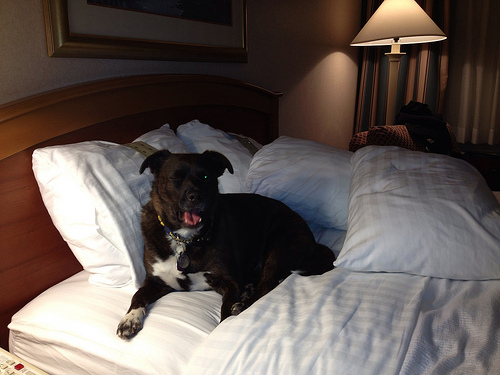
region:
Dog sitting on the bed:
[116, 161, 343, 338]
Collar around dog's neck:
[152, 198, 215, 253]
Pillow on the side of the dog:
[29, 116, 206, 282]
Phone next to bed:
[0, 340, 43, 374]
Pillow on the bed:
[344, 133, 497, 283]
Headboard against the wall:
[0, 75, 296, 350]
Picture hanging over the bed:
[32, 2, 268, 71]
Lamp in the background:
[352, 3, 441, 137]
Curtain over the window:
[442, 3, 497, 154]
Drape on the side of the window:
[354, 1, 454, 151]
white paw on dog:
[118, 291, 165, 346]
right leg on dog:
[128, 275, 173, 332]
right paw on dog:
[101, 294, 149, 349]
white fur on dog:
[143, 260, 190, 279]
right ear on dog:
[139, 155, 186, 177]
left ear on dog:
[209, 144, 238, 169]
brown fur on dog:
[158, 174, 187, 214]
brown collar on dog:
[160, 220, 199, 254]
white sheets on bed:
[230, 312, 379, 368]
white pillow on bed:
[331, 162, 458, 289]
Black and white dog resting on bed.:
[115, 148, 334, 341]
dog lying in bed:
[113, 143, 343, 341]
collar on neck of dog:
[148, 204, 224, 279]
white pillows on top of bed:
[29, 120, 497, 302]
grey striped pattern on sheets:
[206, 285, 383, 373]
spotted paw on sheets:
[105, 300, 157, 344]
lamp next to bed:
[340, 0, 457, 143]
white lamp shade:
[343, 0, 458, 57]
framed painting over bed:
[36, 0, 272, 74]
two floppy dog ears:
[128, 143, 246, 178]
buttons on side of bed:
[2, 345, 48, 373]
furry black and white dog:
[113, 145, 347, 347]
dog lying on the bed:
[126, 144, 338, 342]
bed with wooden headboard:
[0, 73, 498, 374]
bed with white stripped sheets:
[0, 67, 497, 372]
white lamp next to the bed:
[348, 3, 447, 132]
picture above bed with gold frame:
[41, 2, 254, 63]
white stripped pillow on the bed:
[331, 138, 499, 284]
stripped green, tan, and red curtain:
[357, 1, 497, 154]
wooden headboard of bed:
[1, 71, 283, 334]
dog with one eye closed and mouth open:
[115, 144, 347, 346]